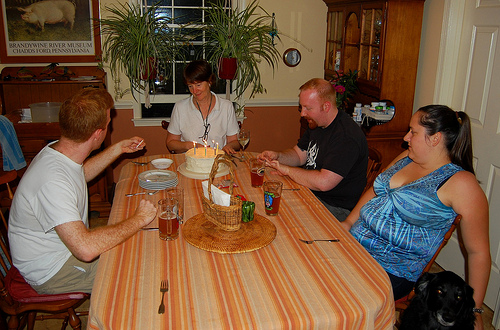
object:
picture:
[0, 6, 101, 64]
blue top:
[346, 157, 459, 282]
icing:
[184, 154, 211, 174]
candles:
[204, 145, 207, 157]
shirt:
[297, 113, 370, 210]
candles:
[193, 141, 196, 155]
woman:
[166, 61, 243, 156]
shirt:
[167, 92, 239, 148]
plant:
[192, 2, 279, 94]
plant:
[96, 0, 191, 96]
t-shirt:
[6, 138, 91, 286]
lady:
[338, 104, 492, 319]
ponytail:
[453, 110, 480, 184]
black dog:
[400, 270, 478, 329]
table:
[88, 151, 395, 329]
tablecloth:
[88, 150, 397, 330]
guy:
[4, 89, 157, 296]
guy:
[259, 78, 368, 220]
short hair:
[59, 97, 107, 141]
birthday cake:
[177, 147, 230, 179]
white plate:
[176, 161, 231, 180]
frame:
[1, 2, 100, 67]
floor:
[429, 261, 449, 272]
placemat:
[182, 212, 276, 255]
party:
[16, 58, 480, 326]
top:
[390, 190, 445, 228]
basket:
[200, 154, 240, 231]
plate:
[137, 170, 177, 183]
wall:
[105, 1, 330, 104]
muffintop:
[359, 200, 425, 255]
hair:
[320, 87, 337, 97]